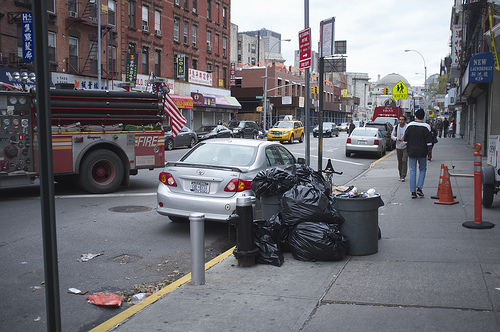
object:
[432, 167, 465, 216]
cones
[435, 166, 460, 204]
cone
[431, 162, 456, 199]
cone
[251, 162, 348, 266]
bags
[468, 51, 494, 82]
sign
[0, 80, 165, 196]
firetruck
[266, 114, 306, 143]
taxi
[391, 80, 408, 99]
pedestrian sign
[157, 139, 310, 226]
sedan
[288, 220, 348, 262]
bag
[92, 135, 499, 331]
sidewalk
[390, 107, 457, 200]
people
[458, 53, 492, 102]
awning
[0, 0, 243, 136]
building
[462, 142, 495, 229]
safety post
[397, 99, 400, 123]
pole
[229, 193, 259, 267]
fire hydrant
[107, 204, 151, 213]
mahole cover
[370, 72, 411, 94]
building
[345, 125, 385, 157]
vehicle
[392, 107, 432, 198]
pedestrians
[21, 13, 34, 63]
sign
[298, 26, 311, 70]
sign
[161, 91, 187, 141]
flag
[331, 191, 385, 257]
garbage can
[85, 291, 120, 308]
rubbish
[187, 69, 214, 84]
sign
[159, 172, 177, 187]
tailight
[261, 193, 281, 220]
trash can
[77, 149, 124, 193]
tire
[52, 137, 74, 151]
stripe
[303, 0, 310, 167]
pole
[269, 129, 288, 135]
grill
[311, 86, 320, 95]
traffic signal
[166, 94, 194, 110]
awning